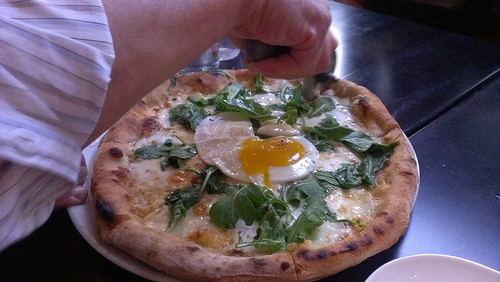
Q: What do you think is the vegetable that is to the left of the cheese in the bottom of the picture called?
A: The vegetable is spinach.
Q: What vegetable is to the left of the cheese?
A: The vegetable is spinach.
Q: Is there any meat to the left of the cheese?
A: No, there is spinach to the left of the cheese.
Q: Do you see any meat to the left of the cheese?
A: No, there is spinach to the left of the cheese.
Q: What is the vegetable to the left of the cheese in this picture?
A: The vegetable is spinach.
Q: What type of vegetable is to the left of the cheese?
A: The vegetable is spinach.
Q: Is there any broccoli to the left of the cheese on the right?
A: No, there is spinach to the left of the cheese.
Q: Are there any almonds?
A: No, there are no almonds.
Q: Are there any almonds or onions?
A: No, there are no almonds or onions.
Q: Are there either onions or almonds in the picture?
A: No, there are no almonds or onions.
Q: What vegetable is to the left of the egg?
A: The vegetable is spinach.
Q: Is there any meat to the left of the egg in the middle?
A: No, there is spinach to the left of the egg.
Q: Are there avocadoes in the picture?
A: No, there are no avocadoes.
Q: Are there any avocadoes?
A: No, there are no avocadoes.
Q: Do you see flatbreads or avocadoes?
A: No, there are no avocadoes or flatbreads.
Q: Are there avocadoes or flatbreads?
A: No, there are no avocadoes or flatbreads.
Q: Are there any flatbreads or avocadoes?
A: No, there are no avocadoes or flatbreads.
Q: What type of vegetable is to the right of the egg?
A: The vegetable is spinach.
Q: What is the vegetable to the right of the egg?
A: The vegetable is spinach.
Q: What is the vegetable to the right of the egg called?
A: The vegetable is spinach.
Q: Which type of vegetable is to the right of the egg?
A: The vegetable is spinach.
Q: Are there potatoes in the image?
A: No, there are no potatoes.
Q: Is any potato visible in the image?
A: No, there are no potatoes.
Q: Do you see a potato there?
A: No, there are no potatoes.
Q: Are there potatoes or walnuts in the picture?
A: No, there are no potatoes or walnuts.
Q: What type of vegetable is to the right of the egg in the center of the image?
A: The vegetable is spinach.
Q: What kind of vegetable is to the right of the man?
A: The vegetable is spinach.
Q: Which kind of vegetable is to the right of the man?
A: The vegetable is spinach.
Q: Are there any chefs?
A: No, there are no chefs.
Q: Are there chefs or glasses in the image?
A: No, there are no chefs or glasses.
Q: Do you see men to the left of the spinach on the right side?
A: Yes, there is a man to the left of the spinach.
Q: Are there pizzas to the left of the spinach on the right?
A: No, there is a man to the left of the spinach.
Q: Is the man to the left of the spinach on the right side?
A: Yes, the man is to the left of the spinach.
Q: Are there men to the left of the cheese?
A: Yes, there is a man to the left of the cheese.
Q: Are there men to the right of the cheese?
A: No, the man is to the left of the cheese.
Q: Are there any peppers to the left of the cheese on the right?
A: No, there is a man to the left of the cheese.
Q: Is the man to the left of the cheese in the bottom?
A: Yes, the man is to the left of the cheese.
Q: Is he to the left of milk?
A: No, the man is to the left of the cheese.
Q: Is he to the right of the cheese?
A: No, the man is to the left of the cheese.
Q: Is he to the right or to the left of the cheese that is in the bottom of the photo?
A: The man is to the left of the cheese.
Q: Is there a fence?
A: No, there are no fences.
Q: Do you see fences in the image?
A: No, there are no fences.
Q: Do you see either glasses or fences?
A: No, there are no fences or glasses.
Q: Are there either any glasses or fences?
A: No, there are no fences or glasses.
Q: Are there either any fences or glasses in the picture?
A: No, there are no fences or glasses.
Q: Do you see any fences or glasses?
A: No, there are no fences or glasses.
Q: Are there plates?
A: Yes, there is a plate.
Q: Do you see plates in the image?
A: Yes, there is a plate.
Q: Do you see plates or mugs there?
A: Yes, there is a plate.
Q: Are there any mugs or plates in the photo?
A: Yes, there is a plate.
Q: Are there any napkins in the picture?
A: No, there are no napkins.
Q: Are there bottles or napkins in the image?
A: No, there are no napkins or bottles.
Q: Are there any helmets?
A: No, there are no helmets.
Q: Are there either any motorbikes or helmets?
A: No, there are no helmets or motorbikes.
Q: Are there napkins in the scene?
A: No, there are no napkins.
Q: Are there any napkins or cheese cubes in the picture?
A: No, there are no napkins or cheese cubes.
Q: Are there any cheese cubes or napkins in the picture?
A: No, there are no napkins or cheese cubes.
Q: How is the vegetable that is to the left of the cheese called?
A: The vegetable is spinach.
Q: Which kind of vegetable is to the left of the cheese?
A: The vegetable is spinach.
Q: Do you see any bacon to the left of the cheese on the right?
A: No, there is spinach to the left of the cheese.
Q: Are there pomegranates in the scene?
A: No, there are no pomegranates.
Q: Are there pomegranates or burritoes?
A: No, there are no pomegranates or burritoes.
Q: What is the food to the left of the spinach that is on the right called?
A: The food is an egg.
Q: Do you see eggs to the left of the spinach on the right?
A: Yes, there is an egg to the left of the spinach.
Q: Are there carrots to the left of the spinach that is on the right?
A: No, there is an egg to the left of the spinach.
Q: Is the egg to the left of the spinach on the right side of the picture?
A: Yes, the egg is to the left of the spinach.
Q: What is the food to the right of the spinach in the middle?
A: The food is an egg.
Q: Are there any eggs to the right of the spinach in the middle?
A: Yes, there is an egg to the right of the spinach.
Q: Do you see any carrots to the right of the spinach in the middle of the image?
A: No, there is an egg to the right of the spinach.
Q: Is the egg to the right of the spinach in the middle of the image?
A: Yes, the egg is to the right of the spinach.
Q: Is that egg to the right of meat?
A: No, the egg is to the right of the spinach.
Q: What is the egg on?
A: The egg is on the spinach.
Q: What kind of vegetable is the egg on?
A: The egg is on the spinach.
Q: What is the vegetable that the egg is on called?
A: The vegetable is spinach.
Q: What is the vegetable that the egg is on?
A: The vegetable is spinach.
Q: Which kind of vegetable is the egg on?
A: The egg is on the spinach.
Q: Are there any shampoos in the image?
A: No, there are no shampoos.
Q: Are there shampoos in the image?
A: No, there are no shampoos.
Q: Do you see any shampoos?
A: No, there are no shampoos.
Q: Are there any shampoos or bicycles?
A: No, there are no shampoos or bicycles.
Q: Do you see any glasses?
A: No, there are no glasses.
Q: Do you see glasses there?
A: No, there are no glasses.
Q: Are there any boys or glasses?
A: No, there are no glasses or boys.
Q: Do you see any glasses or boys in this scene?
A: No, there are no glasses or boys.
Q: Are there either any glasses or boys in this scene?
A: No, there are no glasses or boys.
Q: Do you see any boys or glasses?
A: No, there are no glasses or boys.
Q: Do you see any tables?
A: Yes, there is a table.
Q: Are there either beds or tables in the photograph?
A: Yes, there is a table.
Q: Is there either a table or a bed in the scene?
A: Yes, there is a table.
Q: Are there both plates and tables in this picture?
A: Yes, there are both a table and a plate.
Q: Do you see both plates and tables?
A: Yes, there are both a table and a plate.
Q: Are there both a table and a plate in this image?
A: Yes, there are both a table and a plate.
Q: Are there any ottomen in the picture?
A: No, there are no ottomen.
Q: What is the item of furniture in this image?
A: The piece of furniture is a table.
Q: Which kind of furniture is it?
A: The piece of furniture is a table.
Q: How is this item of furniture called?
A: This is a table.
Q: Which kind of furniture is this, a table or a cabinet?
A: This is a table.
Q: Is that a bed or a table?
A: That is a table.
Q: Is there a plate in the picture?
A: Yes, there is a plate.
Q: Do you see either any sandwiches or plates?
A: Yes, there is a plate.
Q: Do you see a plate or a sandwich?
A: Yes, there is a plate.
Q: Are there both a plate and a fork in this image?
A: No, there is a plate but no forks.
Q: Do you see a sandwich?
A: No, there are no sandwiches.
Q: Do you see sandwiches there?
A: No, there are no sandwiches.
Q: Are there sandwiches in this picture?
A: No, there are no sandwiches.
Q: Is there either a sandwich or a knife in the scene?
A: No, there are no sandwiches or knives.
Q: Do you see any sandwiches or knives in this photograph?
A: No, there are no sandwiches or knives.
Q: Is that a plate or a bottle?
A: That is a plate.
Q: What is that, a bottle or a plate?
A: That is a plate.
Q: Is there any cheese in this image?
A: Yes, there is cheese.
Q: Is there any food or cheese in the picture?
A: Yes, there is cheese.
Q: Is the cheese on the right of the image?
A: Yes, the cheese is on the right of the image.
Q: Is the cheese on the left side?
A: No, the cheese is on the right of the image.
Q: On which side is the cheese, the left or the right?
A: The cheese is on the right of the image.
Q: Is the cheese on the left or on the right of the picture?
A: The cheese is on the right of the image.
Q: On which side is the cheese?
A: The cheese is on the right of the image.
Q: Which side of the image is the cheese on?
A: The cheese is on the right of the image.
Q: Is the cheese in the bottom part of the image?
A: Yes, the cheese is in the bottom of the image.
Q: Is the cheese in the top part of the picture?
A: No, the cheese is in the bottom of the image.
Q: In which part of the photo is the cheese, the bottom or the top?
A: The cheese is in the bottom of the image.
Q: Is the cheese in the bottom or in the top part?
A: The cheese is in the bottom of the image.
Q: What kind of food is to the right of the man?
A: The food is cheese.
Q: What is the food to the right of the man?
A: The food is cheese.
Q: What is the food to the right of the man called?
A: The food is cheese.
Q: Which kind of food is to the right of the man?
A: The food is cheese.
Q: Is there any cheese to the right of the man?
A: Yes, there is cheese to the right of the man.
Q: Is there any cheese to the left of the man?
A: No, the cheese is to the right of the man.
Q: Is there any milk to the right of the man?
A: No, there is cheese to the right of the man.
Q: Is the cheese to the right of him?
A: Yes, the cheese is to the right of a man.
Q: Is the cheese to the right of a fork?
A: No, the cheese is to the right of a man.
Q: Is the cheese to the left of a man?
A: No, the cheese is to the right of a man.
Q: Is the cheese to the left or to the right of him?
A: The cheese is to the right of the man.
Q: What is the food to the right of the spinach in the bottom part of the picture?
A: The food is cheese.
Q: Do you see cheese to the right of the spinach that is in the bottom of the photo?
A: Yes, there is cheese to the right of the spinach.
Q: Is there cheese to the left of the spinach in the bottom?
A: No, the cheese is to the right of the spinach.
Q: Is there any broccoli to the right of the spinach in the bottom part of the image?
A: No, there is cheese to the right of the spinach.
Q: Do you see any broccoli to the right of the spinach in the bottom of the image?
A: No, there is cheese to the right of the spinach.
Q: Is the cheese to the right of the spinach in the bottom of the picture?
A: Yes, the cheese is to the right of the spinach.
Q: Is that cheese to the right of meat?
A: No, the cheese is to the right of the spinach.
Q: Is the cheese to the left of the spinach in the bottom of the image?
A: No, the cheese is to the right of the spinach.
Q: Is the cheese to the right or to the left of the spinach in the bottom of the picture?
A: The cheese is to the right of the spinach.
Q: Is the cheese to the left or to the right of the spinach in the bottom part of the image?
A: The cheese is to the right of the spinach.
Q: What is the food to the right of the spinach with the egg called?
A: The food is cheese.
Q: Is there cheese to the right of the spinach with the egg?
A: Yes, there is cheese to the right of the spinach.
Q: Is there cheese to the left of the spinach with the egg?
A: No, the cheese is to the right of the spinach.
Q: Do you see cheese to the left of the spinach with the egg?
A: No, the cheese is to the right of the spinach.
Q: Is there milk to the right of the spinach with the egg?
A: No, there is cheese to the right of the spinach.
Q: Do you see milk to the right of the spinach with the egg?
A: No, there is cheese to the right of the spinach.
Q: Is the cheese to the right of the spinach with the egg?
A: Yes, the cheese is to the right of the spinach.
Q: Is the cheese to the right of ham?
A: No, the cheese is to the right of the spinach.